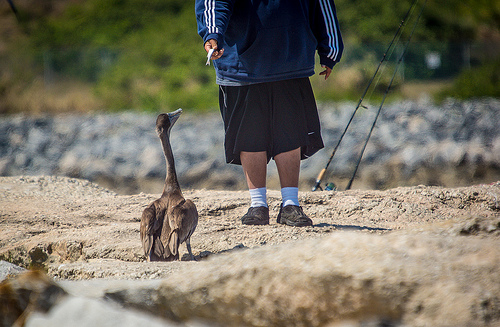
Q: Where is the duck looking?
A: Up.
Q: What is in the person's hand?
A: A fish.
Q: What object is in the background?
A: Fishing pole.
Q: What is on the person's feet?
A: Shoes.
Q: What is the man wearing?
A: Shorts.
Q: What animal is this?
A: Bird.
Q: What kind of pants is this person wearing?
A: Shorts.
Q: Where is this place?
A: The beach.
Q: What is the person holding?
A: Fish.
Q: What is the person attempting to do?
A: Feed the bird.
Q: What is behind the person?
A: Fishing equipment.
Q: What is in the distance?
A: Rock pile.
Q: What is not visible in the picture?
A: The ocean.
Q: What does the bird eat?
A: Fish.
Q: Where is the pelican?
A: On the ground.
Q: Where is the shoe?
A: On the ground.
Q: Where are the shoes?
A: On the ground.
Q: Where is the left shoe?
A: On the ground.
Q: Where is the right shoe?
A: On the ground.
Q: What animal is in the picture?
A: Bird.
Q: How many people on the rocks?
A: One.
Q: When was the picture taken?
A: Daytime.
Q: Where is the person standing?
A: On rocks.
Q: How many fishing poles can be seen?
A: Two.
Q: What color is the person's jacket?
A: Blue.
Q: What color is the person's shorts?
A: Black.